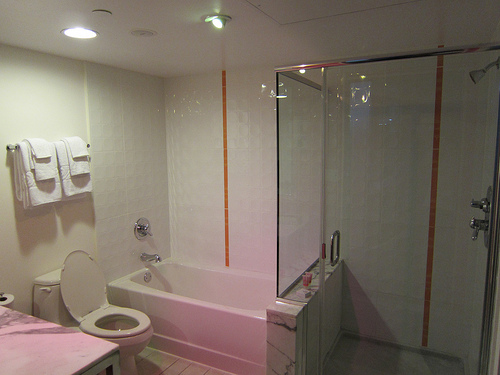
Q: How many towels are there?
A: Six.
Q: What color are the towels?
A: White.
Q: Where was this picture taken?
A: A bathroom.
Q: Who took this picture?
A: The homeowner.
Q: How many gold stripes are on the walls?
A: Two.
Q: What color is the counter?
A: Pink.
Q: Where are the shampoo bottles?
A: In the shower.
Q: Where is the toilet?
A: Next to the bathtub.